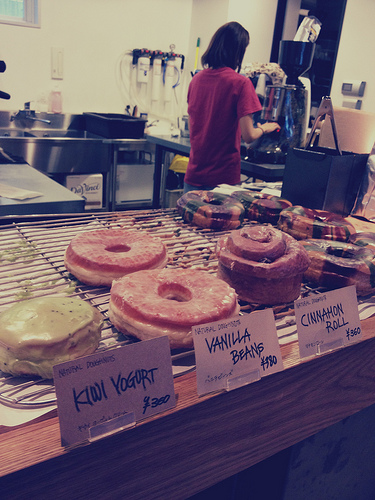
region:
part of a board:
[154, 436, 175, 469]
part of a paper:
[83, 390, 118, 436]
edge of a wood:
[39, 435, 105, 493]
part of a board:
[84, 372, 110, 405]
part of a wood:
[171, 443, 196, 470]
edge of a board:
[45, 406, 90, 461]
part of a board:
[173, 437, 204, 470]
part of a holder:
[111, 410, 143, 440]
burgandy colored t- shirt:
[187, 58, 273, 170]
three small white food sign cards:
[38, 333, 373, 395]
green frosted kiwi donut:
[10, 288, 102, 372]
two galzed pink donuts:
[79, 198, 231, 317]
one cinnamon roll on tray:
[224, 224, 304, 290]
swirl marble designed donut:
[212, 170, 342, 230]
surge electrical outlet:
[126, 39, 191, 99]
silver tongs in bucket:
[293, 98, 373, 157]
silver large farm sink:
[28, 106, 105, 156]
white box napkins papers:
[72, 161, 120, 220]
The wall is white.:
[42, 2, 202, 57]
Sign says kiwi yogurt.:
[50, 335, 171, 425]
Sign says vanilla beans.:
[188, 318, 278, 380]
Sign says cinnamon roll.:
[291, 292, 361, 354]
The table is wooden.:
[37, 360, 292, 466]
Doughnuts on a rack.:
[13, 179, 365, 350]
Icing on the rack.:
[136, 215, 198, 272]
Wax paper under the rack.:
[0, 370, 51, 426]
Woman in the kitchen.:
[177, 9, 264, 190]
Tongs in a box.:
[288, 85, 361, 199]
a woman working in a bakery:
[182, 19, 281, 189]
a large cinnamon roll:
[213, 223, 303, 301]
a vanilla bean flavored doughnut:
[60, 225, 165, 283]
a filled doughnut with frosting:
[0, 291, 103, 378]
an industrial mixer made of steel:
[241, 11, 321, 161]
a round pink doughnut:
[105, 266, 240, 343]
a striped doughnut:
[174, 188, 243, 226]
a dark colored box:
[279, 142, 367, 213]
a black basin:
[78, 108, 145, 138]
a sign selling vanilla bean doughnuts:
[192, 307, 284, 397]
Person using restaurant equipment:
[182, 19, 276, 186]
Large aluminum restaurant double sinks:
[0, 110, 108, 216]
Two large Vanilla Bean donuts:
[64, 228, 239, 348]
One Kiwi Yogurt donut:
[1, 294, 104, 379]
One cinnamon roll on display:
[216, 224, 307, 304]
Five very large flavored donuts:
[175, 189, 374, 296]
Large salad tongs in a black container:
[280, 94, 368, 218]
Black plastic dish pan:
[81, 110, 149, 138]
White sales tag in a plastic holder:
[190, 307, 284, 397]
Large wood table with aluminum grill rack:
[1, 189, 374, 498]